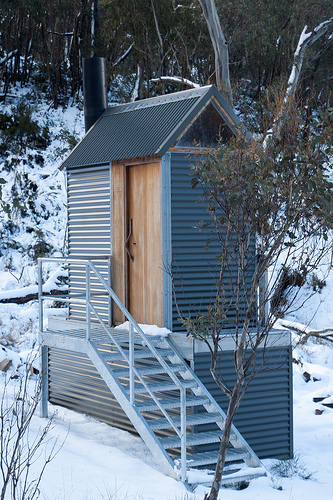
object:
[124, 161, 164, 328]
door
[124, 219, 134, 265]
handle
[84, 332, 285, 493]
stairs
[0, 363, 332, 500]
ground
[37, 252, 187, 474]
rail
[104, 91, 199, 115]
rivets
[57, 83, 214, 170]
roof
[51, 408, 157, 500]
snow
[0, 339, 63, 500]
bushes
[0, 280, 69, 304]
log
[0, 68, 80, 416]
hill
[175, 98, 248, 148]
window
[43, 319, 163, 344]
landing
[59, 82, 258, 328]
cabin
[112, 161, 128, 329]
inset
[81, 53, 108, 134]
chimney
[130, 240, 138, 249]
lock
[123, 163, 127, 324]
door trim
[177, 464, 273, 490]
step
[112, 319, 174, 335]
doorstep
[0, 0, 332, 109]
trees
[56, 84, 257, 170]
roof